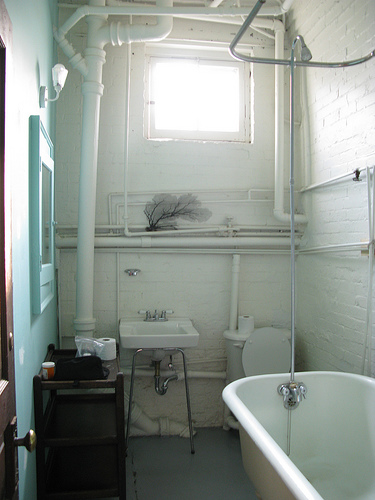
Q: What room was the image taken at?
A: It was taken at the bathroom.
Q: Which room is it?
A: It is a bathroom.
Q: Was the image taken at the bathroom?
A: Yes, it was taken in the bathroom.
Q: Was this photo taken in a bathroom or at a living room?
A: It was taken at a bathroom.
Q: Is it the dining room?
A: No, it is the bathroom.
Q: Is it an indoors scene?
A: Yes, it is indoors.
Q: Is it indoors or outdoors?
A: It is indoors.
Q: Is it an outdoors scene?
A: No, it is indoors.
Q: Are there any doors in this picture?
A: Yes, there is a door.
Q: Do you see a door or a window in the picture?
A: Yes, there is a door.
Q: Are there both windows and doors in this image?
A: Yes, there are both a door and a window.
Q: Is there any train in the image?
A: No, there are no trains.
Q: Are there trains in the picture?
A: No, there are no trains.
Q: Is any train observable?
A: No, there are no trains.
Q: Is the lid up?
A: Yes, the lid is up.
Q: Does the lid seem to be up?
A: Yes, the lid is up.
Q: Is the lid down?
A: No, the lid is up.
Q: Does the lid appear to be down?
A: No, the lid is up.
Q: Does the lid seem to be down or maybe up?
A: The lid is up.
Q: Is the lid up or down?
A: The lid is up.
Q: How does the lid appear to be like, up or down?
A: The lid is up.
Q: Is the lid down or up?
A: The lid is up.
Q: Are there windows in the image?
A: Yes, there is a window.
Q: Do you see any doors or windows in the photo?
A: Yes, there is a window.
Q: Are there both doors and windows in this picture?
A: Yes, there are both a window and a door.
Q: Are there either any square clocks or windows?
A: Yes, there is a square window.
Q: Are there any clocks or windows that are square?
A: Yes, the window is square.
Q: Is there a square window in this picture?
A: Yes, there is a square window.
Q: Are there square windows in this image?
A: Yes, there is a square window.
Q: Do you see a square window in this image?
A: Yes, there is a square window.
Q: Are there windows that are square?
A: Yes, there is a window that is square.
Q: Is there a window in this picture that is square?
A: Yes, there is a window that is square.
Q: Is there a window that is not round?
A: Yes, there is a square window.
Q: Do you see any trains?
A: No, there are no trains.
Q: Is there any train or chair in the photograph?
A: No, there are no trains or chairs.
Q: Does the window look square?
A: Yes, the window is square.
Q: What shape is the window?
A: The window is square.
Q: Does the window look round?
A: No, the window is square.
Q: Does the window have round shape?
A: No, the window is square.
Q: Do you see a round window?
A: No, there is a window but it is square.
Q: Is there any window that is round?
A: No, there is a window but it is square.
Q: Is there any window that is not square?
A: No, there is a window but it is square.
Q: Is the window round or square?
A: The window is square.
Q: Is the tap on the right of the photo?
A: Yes, the tap is on the right of the image.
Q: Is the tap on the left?
A: No, the tap is on the right of the image.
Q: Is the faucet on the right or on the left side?
A: The faucet is on the right of the image.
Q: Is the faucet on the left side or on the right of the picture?
A: The faucet is on the right of the image.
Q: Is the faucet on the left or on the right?
A: The faucet is on the right of the image.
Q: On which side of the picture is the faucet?
A: The faucet is on the right of the image.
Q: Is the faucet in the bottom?
A: Yes, the faucet is in the bottom of the image.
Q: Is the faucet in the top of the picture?
A: No, the faucet is in the bottom of the image.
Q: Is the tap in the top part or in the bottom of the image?
A: The tap is in the bottom of the image.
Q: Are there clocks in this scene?
A: No, there are no clocks.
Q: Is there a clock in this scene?
A: No, there are no clocks.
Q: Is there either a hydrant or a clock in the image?
A: No, there are no clocks or fire hydrants.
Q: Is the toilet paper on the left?
A: Yes, the toilet paper is on the left of the image.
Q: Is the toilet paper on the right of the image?
A: No, the toilet paper is on the left of the image.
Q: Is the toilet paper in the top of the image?
A: No, the toilet paper is in the bottom of the image.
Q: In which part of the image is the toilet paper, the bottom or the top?
A: The toilet paper is in the bottom of the image.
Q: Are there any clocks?
A: No, there are no clocks.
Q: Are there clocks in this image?
A: No, there are no clocks.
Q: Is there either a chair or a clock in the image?
A: No, there are no clocks or chairs.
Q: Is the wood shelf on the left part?
A: Yes, the shelf is on the left of the image.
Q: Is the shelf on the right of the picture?
A: No, the shelf is on the left of the image.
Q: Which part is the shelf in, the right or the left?
A: The shelf is on the left of the image.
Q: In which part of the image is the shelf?
A: The shelf is on the left of the image.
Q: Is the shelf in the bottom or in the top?
A: The shelf is in the bottom of the image.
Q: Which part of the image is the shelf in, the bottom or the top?
A: The shelf is in the bottom of the image.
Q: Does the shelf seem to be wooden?
A: Yes, the shelf is wooden.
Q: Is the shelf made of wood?
A: Yes, the shelf is made of wood.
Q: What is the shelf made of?
A: The shelf is made of wood.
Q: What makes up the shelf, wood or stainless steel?
A: The shelf is made of wood.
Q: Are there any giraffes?
A: No, there are no giraffes.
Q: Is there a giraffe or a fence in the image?
A: No, there are no giraffes or fences.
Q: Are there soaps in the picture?
A: No, there are no soaps.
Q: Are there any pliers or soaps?
A: No, there are no soaps or pliers.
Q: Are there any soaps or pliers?
A: No, there are no soaps or pliers.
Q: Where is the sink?
A: The sink is in the bathroom.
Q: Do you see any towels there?
A: No, there are no towels.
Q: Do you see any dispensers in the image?
A: No, there are no dispensers.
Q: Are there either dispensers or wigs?
A: No, there are no dispensers or wigs.